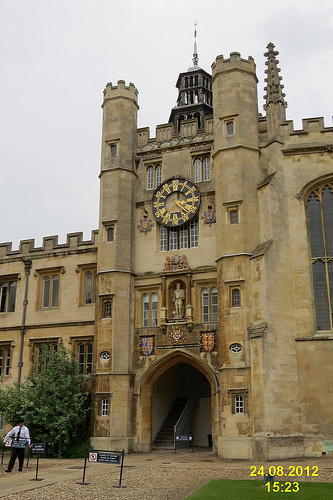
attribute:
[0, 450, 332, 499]
pavement — cobblestone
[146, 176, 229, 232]
clock — large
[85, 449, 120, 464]
sign — red, white, forbidden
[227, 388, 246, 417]
window — small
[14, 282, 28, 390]
pipe — black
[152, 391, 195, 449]
staircase — concrete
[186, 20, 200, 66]
metal spire — decorative , metal 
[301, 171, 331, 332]
window — huge, decorative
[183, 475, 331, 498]
grass — green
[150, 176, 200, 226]
clock — gold, large